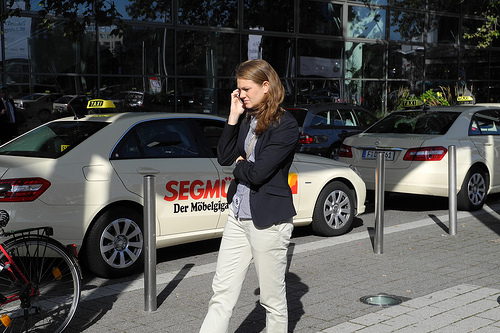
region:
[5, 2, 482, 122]
reflection on building window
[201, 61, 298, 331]
walking woman on phone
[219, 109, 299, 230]
blue jacket on woman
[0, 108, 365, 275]
side of white car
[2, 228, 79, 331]
back tire of bike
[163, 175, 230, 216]
words on car door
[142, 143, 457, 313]
silver metal poles on sidewalk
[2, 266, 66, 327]
yellow reflectors on spokes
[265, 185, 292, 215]
pocket on side of jacket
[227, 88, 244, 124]
hand holding phone to head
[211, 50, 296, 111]
woman has brown hair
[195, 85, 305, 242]
woman has blue coat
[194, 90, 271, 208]
woman has blue shirt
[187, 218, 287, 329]
woman has grey pants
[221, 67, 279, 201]
woman is talking on cell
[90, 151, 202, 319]
metal poles behind woman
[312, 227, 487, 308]
sidewalk is dark grey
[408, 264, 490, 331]
sidewalk is light grey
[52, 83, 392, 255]
white car parked on curb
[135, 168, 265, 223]
red and black company name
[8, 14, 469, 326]
Photo taken during the day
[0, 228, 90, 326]
Bike wheel on the sidewalk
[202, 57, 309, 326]
Woman on a cell phone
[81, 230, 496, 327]
Concrete pavers on the sidewalk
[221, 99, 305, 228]
Black jacket on the woman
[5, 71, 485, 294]
Two white sedans on the road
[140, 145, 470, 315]
Metal posts lining the street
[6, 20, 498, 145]
Many windows on the building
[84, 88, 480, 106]
Taxi cab signs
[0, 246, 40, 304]
Red bike frame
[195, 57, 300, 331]
women wearing dark blue jacket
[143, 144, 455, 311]
silver metal poles in sidewalk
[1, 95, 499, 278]
two white metal cars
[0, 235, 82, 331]
black and silver bicycle tire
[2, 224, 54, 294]
black metal bicycle rack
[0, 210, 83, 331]
red metal bicycle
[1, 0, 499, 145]
clear reflective glass building windows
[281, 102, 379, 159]
dark gray metal car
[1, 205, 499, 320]
white paint line on gray road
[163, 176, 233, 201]
red painted text on white car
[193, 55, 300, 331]
Woman wearing blue blazer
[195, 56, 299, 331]
Woman wearing white pants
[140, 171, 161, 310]
Metal pole next to car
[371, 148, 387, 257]
Metal pole next to car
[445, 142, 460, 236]
Metal pole next to car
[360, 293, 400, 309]
Light on ground behind woman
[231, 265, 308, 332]
Shadow of woman on ground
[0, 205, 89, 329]
Bike in front of pole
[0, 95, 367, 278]
Taxi is parked behind taxi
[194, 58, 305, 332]
Woman is using cell phone